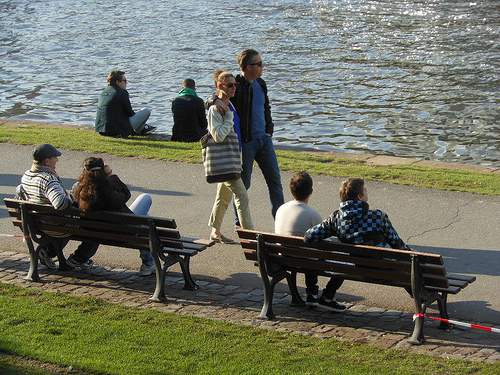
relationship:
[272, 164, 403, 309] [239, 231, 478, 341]
men sitting on a beach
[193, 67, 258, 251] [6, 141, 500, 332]
woman walking on sidewalk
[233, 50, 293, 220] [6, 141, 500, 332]
man walking on sidewalk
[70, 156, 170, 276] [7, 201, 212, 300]
people on bench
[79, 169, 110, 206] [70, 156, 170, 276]
hair of people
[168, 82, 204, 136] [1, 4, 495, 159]
man sitting next to lake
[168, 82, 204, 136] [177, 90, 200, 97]
man wearing green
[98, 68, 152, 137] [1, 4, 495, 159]
man sitting next to lake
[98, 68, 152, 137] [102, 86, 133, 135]
man wearing jacket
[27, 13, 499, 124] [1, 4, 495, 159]
ripples in lake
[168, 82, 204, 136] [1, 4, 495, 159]
man sitting by lake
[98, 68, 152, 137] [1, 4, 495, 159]
man sitting by lake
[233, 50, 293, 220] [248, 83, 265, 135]
man wearing shirt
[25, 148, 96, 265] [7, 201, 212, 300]
person sitting on bench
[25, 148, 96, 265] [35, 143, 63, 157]
person wearing a cap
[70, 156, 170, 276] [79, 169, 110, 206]
people has hair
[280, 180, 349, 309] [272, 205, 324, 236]
person wearing shirt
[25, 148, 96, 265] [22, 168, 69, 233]
person wearing a jacket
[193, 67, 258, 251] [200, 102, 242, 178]
woman carrying purse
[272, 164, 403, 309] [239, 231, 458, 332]
men sitting on a bench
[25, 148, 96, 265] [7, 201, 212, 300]
person sitting on a bench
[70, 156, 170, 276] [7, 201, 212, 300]
people sitting on a bench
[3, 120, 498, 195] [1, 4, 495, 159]
grass by lake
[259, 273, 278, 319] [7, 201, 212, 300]
leg of bench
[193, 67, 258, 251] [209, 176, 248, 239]
woman wearing pants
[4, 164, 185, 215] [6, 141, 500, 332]
shadow on sidewalk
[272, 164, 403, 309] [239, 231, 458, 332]
men sitting on bench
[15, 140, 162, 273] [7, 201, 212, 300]
people sitting on bench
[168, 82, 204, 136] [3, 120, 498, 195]
man sitting on grass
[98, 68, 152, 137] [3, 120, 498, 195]
man sitting on grass